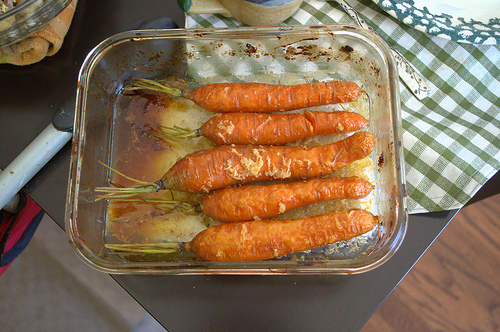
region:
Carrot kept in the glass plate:
[126, 47, 382, 239]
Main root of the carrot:
[360, 86, 380, 114]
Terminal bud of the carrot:
[98, 158, 143, 253]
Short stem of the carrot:
[155, 170, 177, 197]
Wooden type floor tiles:
[455, 258, 492, 312]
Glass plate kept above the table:
[81, 40, 118, 211]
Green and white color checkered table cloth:
[434, 55, 483, 182]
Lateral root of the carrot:
[293, 142, 358, 169]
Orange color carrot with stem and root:
[107, 72, 382, 272]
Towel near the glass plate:
[32, 34, 64, 60]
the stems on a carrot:
[127, 71, 194, 108]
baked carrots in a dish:
[120, 59, 383, 243]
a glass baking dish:
[82, 34, 405, 276]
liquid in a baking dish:
[85, 87, 172, 246]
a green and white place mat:
[422, 68, 493, 160]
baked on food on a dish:
[218, 38, 365, 63]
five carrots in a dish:
[180, 52, 383, 274]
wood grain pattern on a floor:
[420, 224, 496, 319]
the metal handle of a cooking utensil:
[335, 5, 430, 104]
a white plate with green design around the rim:
[372, 0, 495, 52]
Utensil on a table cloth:
[333, 0, 431, 100]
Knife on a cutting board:
[1, 17, 180, 248]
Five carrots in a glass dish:
[72, 23, 405, 273]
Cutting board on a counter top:
[2, 0, 460, 330]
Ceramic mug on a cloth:
[176, 0, 306, 26]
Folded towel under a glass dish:
[0, 3, 80, 62]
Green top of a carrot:
[98, 163, 160, 198]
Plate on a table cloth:
[369, 0, 498, 42]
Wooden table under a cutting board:
[348, 145, 495, 327]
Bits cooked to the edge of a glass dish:
[162, 40, 372, 66]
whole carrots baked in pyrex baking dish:
[65, 25, 407, 272]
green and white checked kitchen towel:
[184, 3, 498, 213]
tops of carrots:
[96, 77, 201, 257]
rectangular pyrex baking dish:
[64, 26, 406, 275]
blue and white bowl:
[372, 0, 497, 43]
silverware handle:
[324, 1, 431, 99]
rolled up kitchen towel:
[1, 0, 76, 64]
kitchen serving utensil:
[1, 15, 182, 208]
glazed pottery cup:
[181, 0, 304, 25]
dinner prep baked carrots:
[1, 1, 499, 329]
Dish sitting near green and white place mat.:
[344, 28, 431, 245]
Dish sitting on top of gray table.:
[56, 140, 293, 330]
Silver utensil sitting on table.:
[395, 52, 437, 125]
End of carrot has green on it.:
[134, 74, 188, 101]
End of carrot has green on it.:
[88, 168, 173, 202]